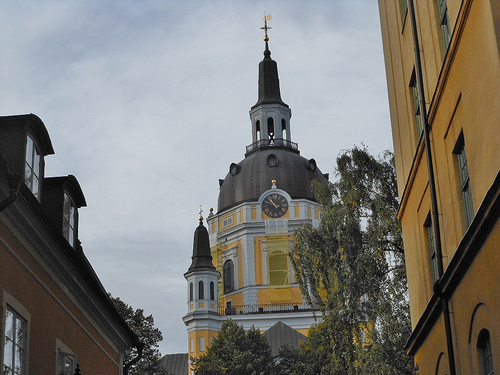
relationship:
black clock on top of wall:
[262, 193, 288, 219] [241, 173, 311, 266]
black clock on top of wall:
[262, 193, 288, 219] [244, 162, 316, 313]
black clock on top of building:
[262, 193, 288, 219] [376, 0, 500, 375]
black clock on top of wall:
[263, 190, 290, 227] [246, 166, 313, 262]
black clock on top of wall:
[262, 193, 288, 219] [248, 147, 318, 243]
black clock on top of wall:
[262, 193, 288, 219] [190, 322, 372, 373]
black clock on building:
[262, 193, 288, 219] [181, 14, 378, 373]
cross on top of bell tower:
[251, 9, 278, 40] [198, 14, 350, 320]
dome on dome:
[197, 121, 390, 243] [217, 146, 332, 214]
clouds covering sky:
[2, 2, 402, 352] [1, 0, 416, 352]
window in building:
[447, 124, 480, 230] [379, 28, 499, 324]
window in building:
[418, 211, 443, 282] [345, 73, 482, 240]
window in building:
[426, 0, 463, 52] [384, 0, 499, 370]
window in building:
[267, 250, 289, 287] [181, 14, 378, 373]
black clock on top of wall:
[262, 193, 288, 219] [245, 195, 310, 313]